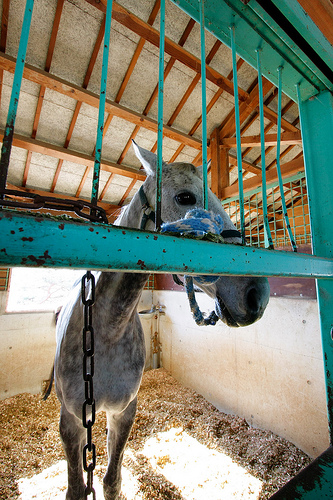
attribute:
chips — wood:
[0, 364, 313, 498]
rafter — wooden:
[115, 23, 144, 111]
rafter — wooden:
[43, 0, 69, 79]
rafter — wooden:
[59, 92, 82, 151]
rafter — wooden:
[28, 73, 49, 139]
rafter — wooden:
[49, 153, 62, 193]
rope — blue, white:
[171, 206, 223, 328]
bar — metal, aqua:
[89, 1, 115, 217]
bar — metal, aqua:
[153, 0, 163, 230]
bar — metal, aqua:
[200, 0, 212, 209]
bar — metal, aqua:
[230, 20, 252, 241]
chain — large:
[0, 165, 120, 230]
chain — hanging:
[3, 183, 124, 220]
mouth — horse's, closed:
[210, 282, 241, 336]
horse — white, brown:
[41, 136, 270, 498]